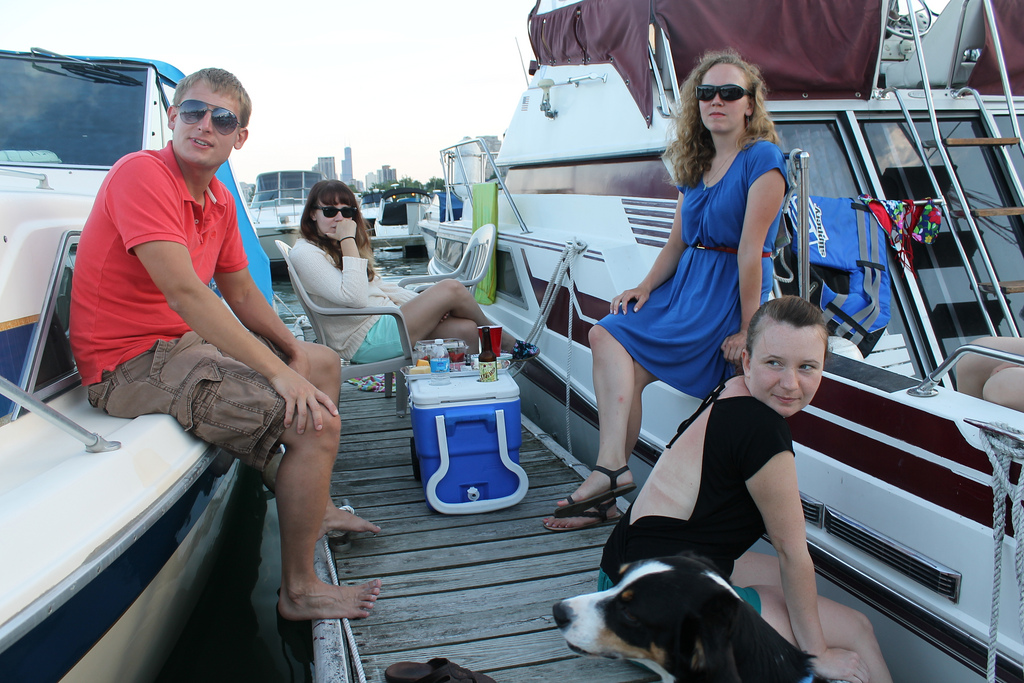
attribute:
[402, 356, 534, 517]
box — blue , white 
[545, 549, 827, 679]
dog — black, white , brown 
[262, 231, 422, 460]
chair — grey 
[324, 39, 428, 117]
sky — white 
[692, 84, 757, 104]
eye glass — black